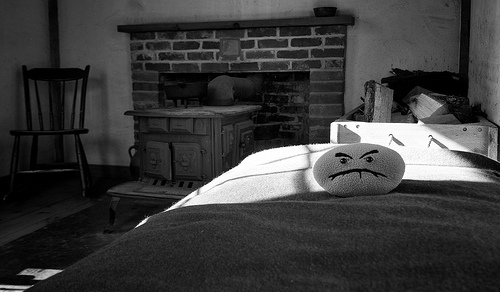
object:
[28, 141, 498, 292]
pillow bed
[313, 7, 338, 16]
bowl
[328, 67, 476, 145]
logs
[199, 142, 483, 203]
sunlight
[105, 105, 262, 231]
dresser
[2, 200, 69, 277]
ground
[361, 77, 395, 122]
firewood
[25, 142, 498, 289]
bed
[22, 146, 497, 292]
sheets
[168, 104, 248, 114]
ash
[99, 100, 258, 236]
wood burner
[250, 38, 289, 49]
brick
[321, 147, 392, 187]
face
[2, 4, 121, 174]
corner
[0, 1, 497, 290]
room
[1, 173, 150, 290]
floor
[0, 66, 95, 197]
chair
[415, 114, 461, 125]
firewood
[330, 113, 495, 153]
box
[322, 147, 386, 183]
design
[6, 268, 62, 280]
sun light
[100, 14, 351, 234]
fire place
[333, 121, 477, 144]
sunlight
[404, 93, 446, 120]
firewood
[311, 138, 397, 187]
face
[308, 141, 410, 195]
pillow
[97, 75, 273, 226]
stove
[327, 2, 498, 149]
corner